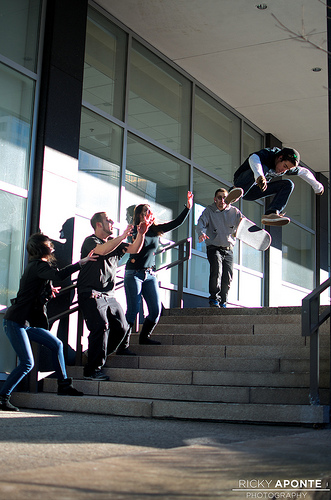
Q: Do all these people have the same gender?
A: No, they are both male and female.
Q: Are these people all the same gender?
A: No, they are both male and female.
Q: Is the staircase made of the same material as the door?
A: No, the staircase is made of cement and the door is made of glass.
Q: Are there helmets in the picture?
A: No, there are no helmets.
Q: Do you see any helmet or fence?
A: No, there are no helmets or fences.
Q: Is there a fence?
A: No, there are no fences.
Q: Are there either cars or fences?
A: No, there are no fences or cars.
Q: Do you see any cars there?
A: No, there are no cars.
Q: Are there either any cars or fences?
A: No, there are no cars or fences.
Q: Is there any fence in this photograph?
A: No, there are no fences.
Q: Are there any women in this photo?
A: Yes, there is a woman.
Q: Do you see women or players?
A: Yes, there is a woman.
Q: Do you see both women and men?
A: Yes, there are both a woman and a man.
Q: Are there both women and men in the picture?
A: Yes, there are both a woman and a man.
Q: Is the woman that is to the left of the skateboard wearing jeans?
A: Yes, the woman is wearing jeans.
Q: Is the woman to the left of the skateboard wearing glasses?
A: No, the woman is wearing jeans.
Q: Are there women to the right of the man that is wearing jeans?
A: Yes, there is a woman to the right of the man.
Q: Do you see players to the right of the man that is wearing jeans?
A: No, there is a woman to the right of the man.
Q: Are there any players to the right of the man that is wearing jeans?
A: No, there is a woman to the right of the man.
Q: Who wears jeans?
A: The woman wears jeans.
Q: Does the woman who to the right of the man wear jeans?
A: Yes, the woman wears jeans.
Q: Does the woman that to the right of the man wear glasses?
A: No, the woman wears jeans.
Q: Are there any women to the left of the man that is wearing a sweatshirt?
A: Yes, there is a woman to the left of the man.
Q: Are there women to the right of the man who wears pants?
A: No, the woman is to the left of the man.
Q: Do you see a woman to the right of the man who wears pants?
A: No, the woman is to the left of the man.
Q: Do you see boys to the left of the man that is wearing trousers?
A: No, there is a woman to the left of the man.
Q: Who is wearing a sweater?
A: The woman is wearing a sweater.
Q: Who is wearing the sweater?
A: The woman is wearing a sweater.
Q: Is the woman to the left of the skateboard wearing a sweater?
A: Yes, the woman is wearing a sweater.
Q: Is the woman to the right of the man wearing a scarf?
A: No, the woman is wearing a sweater.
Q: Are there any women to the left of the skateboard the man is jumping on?
A: Yes, there is a woman to the left of the skateboard.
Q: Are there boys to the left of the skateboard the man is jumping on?
A: No, there is a woman to the left of the skateboard.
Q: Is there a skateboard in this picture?
A: Yes, there is a skateboard.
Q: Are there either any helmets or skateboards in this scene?
A: Yes, there is a skateboard.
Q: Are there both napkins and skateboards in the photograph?
A: No, there is a skateboard but no napkins.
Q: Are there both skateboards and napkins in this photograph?
A: No, there is a skateboard but no napkins.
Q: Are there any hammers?
A: No, there are no hammers.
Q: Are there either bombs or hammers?
A: No, there are no hammers or bombs.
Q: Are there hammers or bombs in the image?
A: No, there are no hammers or bombs.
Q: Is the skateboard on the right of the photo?
A: Yes, the skateboard is on the right of the image.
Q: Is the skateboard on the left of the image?
A: No, the skateboard is on the right of the image.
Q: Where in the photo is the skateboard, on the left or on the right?
A: The skateboard is on the right of the image.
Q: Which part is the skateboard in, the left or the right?
A: The skateboard is on the right of the image.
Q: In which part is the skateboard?
A: The skateboard is on the right of the image.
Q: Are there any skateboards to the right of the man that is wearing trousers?
A: Yes, there is a skateboard to the right of the man.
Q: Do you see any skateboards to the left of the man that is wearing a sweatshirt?
A: No, the skateboard is to the right of the man.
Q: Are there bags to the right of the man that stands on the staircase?
A: No, there is a skateboard to the right of the man.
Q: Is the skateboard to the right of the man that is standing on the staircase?
A: Yes, the skateboard is to the right of the man.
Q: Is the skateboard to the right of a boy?
A: No, the skateboard is to the right of the man.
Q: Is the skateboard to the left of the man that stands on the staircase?
A: No, the skateboard is to the right of the man.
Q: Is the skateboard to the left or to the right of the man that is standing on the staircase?
A: The skateboard is to the right of the man.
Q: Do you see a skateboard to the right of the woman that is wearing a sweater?
A: Yes, there is a skateboard to the right of the woman.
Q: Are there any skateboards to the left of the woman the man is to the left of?
A: No, the skateboard is to the right of the woman.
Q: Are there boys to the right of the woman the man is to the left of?
A: No, there is a skateboard to the right of the woman.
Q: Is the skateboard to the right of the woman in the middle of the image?
A: Yes, the skateboard is to the right of the woman.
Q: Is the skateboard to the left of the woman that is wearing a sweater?
A: No, the skateboard is to the right of the woman.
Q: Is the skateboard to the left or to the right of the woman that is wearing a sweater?
A: The skateboard is to the right of the woman.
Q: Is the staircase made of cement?
A: Yes, the staircase is made of cement.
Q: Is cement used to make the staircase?
A: Yes, the staircase is made of cement.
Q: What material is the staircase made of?
A: The staircase is made of cement.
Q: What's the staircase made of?
A: The staircase is made of concrete.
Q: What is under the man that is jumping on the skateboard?
A: The staircase is under the man.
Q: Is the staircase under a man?
A: Yes, the staircase is under a man.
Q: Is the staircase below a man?
A: Yes, the staircase is below a man.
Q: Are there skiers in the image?
A: No, there are no skiers.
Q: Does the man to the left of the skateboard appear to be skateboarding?
A: Yes, the man is skateboarding.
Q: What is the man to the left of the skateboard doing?
A: The man is skateboarding.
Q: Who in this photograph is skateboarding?
A: The man is skateboarding.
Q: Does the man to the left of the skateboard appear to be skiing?
A: No, the man is skateboarding.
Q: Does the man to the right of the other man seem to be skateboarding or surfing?
A: The man is skateboarding.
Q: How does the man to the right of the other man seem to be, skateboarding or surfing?
A: The man is skateboarding.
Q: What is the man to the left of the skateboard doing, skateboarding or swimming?
A: The man is skateboarding.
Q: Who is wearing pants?
A: The man is wearing pants.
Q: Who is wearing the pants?
A: The man is wearing pants.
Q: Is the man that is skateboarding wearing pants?
A: Yes, the man is wearing pants.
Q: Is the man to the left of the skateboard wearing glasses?
A: No, the man is wearing pants.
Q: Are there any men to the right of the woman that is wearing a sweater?
A: Yes, there is a man to the right of the woman.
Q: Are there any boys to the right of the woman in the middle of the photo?
A: No, there is a man to the right of the woman.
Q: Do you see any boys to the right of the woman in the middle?
A: No, there is a man to the right of the woman.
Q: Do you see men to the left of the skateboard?
A: Yes, there is a man to the left of the skateboard.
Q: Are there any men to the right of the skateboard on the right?
A: No, the man is to the left of the skateboard.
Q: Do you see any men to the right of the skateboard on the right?
A: No, the man is to the left of the skateboard.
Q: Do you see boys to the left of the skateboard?
A: No, there is a man to the left of the skateboard.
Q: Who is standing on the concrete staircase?
A: The man is standing on the staircase.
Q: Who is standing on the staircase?
A: The man is standing on the staircase.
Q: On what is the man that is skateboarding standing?
A: The man is standing on the staircase.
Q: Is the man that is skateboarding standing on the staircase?
A: Yes, the man is standing on the staircase.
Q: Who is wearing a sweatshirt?
A: The man is wearing a sweatshirt.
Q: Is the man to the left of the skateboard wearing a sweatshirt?
A: Yes, the man is wearing a sweatshirt.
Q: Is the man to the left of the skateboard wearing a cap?
A: No, the man is wearing a sweatshirt.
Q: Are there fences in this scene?
A: No, there are no fences.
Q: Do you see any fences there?
A: No, there are no fences.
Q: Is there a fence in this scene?
A: No, there are no fences.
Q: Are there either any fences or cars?
A: No, there are no fences or cars.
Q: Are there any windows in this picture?
A: Yes, there is a window.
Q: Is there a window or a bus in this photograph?
A: Yes, there is a window.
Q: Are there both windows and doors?
A: Yes, there are both a window and a door.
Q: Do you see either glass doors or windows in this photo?
A: Yes, there is a glass window.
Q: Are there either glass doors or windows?
A: Yes, there is a glass window.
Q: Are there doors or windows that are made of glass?
A: Yes, the window is made of glass.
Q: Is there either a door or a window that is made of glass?
A: Yes, the window is made of glass.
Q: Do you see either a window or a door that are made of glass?
A: Yes, the window is made of glass.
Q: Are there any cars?
A: No, there are no cars.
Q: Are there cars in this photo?
A: No, there are no cars.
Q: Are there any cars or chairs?
A: No, there are no cars or chairs.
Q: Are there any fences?
A: No, there are no fences.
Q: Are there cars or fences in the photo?
A: No, there are no fences or cars.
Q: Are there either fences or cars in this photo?
A: No, there are no fences or cars.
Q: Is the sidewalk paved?
A: Yes, the sidewalk is paved.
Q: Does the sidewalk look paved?
A: Yes, the sidewalk is paved.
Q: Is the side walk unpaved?
A: No, the side walk is paved.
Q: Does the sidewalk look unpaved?
A: No, the sidewalk is paved.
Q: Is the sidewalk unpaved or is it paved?
A: The sidewalk is paved.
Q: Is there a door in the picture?
A: Yes, there is a door.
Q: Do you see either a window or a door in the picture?
A: Yes, there is a door.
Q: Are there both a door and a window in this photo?
A: Yes, there are both a door and a window.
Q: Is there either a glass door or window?
A: Yes, there is a glass door.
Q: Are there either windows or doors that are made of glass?
A: Yes, the door is made of glass.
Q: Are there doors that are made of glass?
A: Yes, there is a door that is made of glass.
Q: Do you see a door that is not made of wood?
A: Yes, there is a door that is made of glass.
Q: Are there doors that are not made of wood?
A: Yes, there is a door that is made of glass.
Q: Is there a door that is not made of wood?
A: Yes, there is a door that is made of glass.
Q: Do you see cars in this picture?
A: No, there are no cars.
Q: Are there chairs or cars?
A: No, there are no cars or chairs.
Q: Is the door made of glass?
A: Yes, the door is made of glass.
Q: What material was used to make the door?
A: The door is made of glass.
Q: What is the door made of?
A: The door is made of glass.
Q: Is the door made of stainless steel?
A: No, the door is made of glass.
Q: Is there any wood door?
A: No, there is a door but it is made of glass.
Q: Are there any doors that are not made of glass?
A: No, there is a door but it is made of glass.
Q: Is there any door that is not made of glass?
A: No, there is a door but it is made of glass.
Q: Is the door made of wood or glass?
A: The door is made of glass.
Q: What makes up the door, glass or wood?
A: The door is made of glass.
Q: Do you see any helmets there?
A: No, there are no helmets.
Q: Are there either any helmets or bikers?
A: No, there are no helmets or bikers.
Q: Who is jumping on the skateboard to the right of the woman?
A: The man is jumping on the skateboard.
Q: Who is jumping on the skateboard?
A: The man is jumping on the skateboard.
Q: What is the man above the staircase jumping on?
A: The man is jumping on the skateboard.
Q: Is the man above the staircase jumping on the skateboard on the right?
A: Yes, the man is jumping on the skateboard.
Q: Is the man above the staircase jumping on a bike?
A: No, the man is jumping on the skateboard.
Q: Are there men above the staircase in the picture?
A: Yes, there is a man above the staircase.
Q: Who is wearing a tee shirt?
A: The man is wearing a tee shirt.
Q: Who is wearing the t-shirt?
A: The man is wearing a tee shirt.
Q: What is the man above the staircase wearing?
A: The man is wearing a t-shirt.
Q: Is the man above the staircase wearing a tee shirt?
A: Yes, the man is wearing a tee shirt.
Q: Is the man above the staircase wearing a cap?
A: No, the man is wearing a tee shirt.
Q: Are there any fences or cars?
A: No, there are no cars or fences.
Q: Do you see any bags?
A: No, there are no bags.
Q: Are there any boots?
A: Yes, there are boots.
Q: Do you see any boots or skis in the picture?
A: Yes, there are boots.